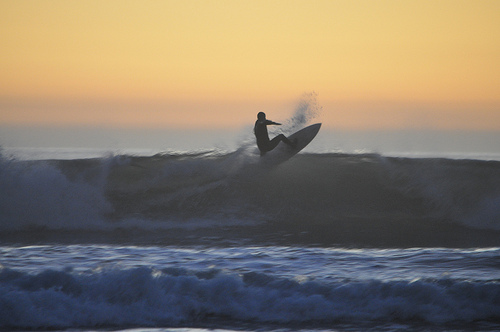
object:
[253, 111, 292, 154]
man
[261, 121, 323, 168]
surfboard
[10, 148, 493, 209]
wave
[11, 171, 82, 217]
foam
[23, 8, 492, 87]
sunset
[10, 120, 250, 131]
horizon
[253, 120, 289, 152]
wetsuit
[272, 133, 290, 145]
leg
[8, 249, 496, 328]
ocean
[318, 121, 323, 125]
tip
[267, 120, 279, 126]
arm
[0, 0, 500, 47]
sky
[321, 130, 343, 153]
air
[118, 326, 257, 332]
shore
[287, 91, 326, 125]
water